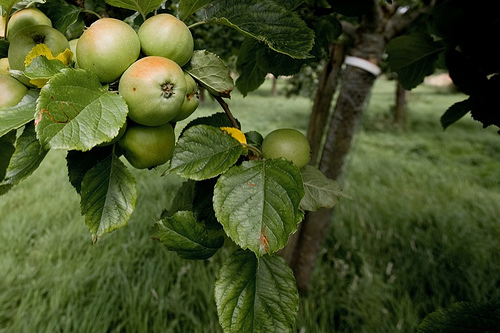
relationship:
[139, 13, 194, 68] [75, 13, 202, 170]
apple in bunch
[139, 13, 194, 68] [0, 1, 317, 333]
apple on tree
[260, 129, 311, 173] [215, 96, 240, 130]
apple on branch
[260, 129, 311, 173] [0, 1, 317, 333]
apple on tree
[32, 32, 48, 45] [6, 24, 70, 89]
stem on apple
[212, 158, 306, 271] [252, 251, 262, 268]
leaf has tip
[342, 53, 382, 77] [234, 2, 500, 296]
band on tree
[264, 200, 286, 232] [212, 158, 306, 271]
vein on leaf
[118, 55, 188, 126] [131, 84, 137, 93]
fruit has spot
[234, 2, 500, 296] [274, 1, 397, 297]
tree has trunk